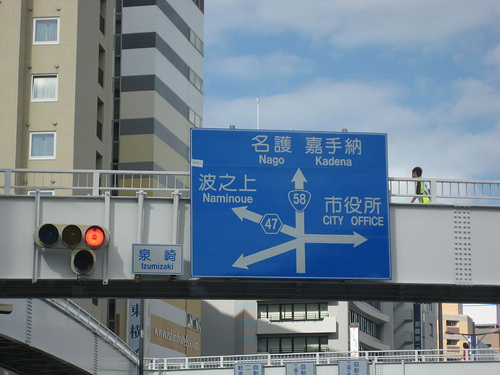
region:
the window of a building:
[32, 77, 59, 103]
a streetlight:
[30, 215, 111, 274]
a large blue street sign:
[184, 126, 396, 281]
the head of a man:
[405, 165, 422, 176]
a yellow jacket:
[415, 180, 426, 200]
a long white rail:
[0, 165, 495, 195]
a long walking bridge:
[0, 200, 495, 296]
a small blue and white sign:
[125, 243, 185, 273]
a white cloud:
[210, 52, 322, 85]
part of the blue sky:
[230, 35, 286, 50]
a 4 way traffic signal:
[33, 219, 106, 274]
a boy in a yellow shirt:
[403, 161, 431, 207]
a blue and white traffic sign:
[187, 122, 391, 286]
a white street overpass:
[1, 165, 498, 309]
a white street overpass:
[141, 347, 494, 372]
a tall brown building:
[6, 0, 201, 197]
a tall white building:
[198, 300, 435, 364]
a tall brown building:
[442, 302, 497, 359]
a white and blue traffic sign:
[129, 243, 182, 276]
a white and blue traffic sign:
[335, 356, 370, 373]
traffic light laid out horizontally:
[34, 220, 106, 250]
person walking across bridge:
[406, 161, 433, 208]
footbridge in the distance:
[148, 336, 497, 372]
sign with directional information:
[182, 125, 391, 280]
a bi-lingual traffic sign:
[188, 131, 392, 277]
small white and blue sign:
[123, 241, 184, 277]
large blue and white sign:
[187, 126, 393, 283]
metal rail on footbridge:
[390, 172, 499, 203]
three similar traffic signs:
[227, 353, 377, 373]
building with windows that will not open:
[115, 4, 206, 183]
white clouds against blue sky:
[226, 6, 491, 120]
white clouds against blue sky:
[386, 14, 492, 159]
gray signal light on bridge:
[31, 219, 111, 256]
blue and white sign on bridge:
[133, 238, 180, 283]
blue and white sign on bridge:
[200, 135, 385, 271]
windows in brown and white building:
[12, 3, 100, 155]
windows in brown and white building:
[131, 13, 189, 171]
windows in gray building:
[221, 300, 398, 342]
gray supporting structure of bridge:
[406, 216, 480, 274]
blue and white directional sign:
[216, 134, 359, 254]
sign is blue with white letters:
[195, 125, 396, 279]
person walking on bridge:
[398, 167, 435, 214]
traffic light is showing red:
[46, 220, 101, 279]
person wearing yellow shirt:
[410, 162, 441, 208]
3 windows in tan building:
[5, 12, 76, 168]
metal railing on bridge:
[99, 160, 176, 205]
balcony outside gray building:
[260, 300, 350, 334]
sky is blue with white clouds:
[423, 130, 478, 165]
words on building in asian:
[153, 310, 208, 365]